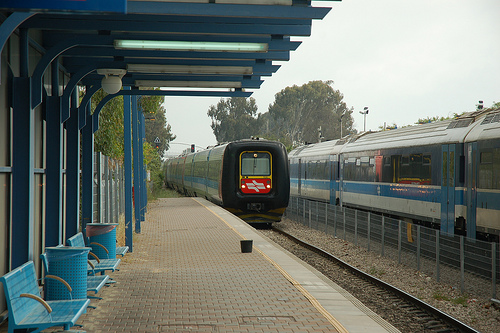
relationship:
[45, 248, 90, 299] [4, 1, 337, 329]
can next to building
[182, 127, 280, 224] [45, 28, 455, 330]
train leaving station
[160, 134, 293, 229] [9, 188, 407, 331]
train approaching platform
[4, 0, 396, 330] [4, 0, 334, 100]
platform with overhang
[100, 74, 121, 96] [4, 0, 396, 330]
globe light on platform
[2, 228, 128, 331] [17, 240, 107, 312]
bench with handles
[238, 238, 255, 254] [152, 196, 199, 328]
black object on ground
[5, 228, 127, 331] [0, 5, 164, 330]
bench next building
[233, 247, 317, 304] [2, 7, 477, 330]
line at train station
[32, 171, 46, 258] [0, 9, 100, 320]
window in building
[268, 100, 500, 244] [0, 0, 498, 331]
freight train leaving station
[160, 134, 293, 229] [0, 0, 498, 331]
train leaving station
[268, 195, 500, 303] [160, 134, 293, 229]
fence between train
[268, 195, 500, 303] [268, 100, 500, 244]
fence between freight train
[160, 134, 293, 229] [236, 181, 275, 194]
train has lights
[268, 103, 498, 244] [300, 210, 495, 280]
freight train parked on track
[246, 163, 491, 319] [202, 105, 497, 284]
fence separates trains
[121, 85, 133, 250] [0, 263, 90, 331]
pole next to bench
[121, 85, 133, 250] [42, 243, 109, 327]
pole next to bench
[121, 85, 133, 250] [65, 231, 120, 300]
pole next to bench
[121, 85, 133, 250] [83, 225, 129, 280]
pole next to bench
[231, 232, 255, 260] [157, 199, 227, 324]
black object on platform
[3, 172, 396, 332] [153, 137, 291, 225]
platform for train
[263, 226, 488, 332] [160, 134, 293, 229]
tracks in front of train